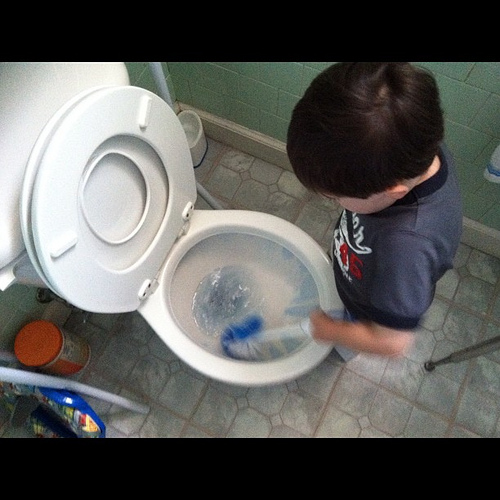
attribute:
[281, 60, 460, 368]
person — cleaning, boy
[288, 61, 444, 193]
hair — brown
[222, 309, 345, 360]
toilet brush — blue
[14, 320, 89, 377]
wet wipes — orange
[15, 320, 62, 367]
lid — orange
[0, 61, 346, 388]
toilet — white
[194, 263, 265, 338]
water — blue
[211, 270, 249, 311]
soap — bubbling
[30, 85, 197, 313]
toilet seat — lifted, white, up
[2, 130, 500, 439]
tile — white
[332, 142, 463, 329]
shirt — blue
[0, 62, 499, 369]
tiles — green